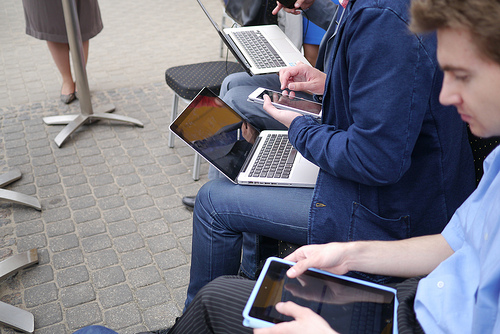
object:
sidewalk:
[1, 0, 225, 334]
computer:
[170, 87, 320, 188]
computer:
[248, 82, 323, 118]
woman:
[23, 0, 103, 106]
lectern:
[46, 0, 142, 146]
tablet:
[241, 254, 413, 332]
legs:
[53, 0, 117, 117]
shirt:
[410, 143, 499, 334]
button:
[436, 281, 444, 288]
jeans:
[186, 161, 362, 294]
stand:
[35, 0, 142, 150]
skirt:
[22, 0, 110, 43]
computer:
[197, 0, 312, 74]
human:
[79, 0, 496, 333]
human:
[179, 0, 480, 303]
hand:
[277, 59, 328, 94]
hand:
[258, 93, 297, 126]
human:
[181, 0, 342, 208]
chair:
[162, 0, 270, 180]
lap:
[189, 179, 280, 240]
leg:
[42, 114, 80, 124]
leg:
[95, 106, 120, 113]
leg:
[93, 114, 146, 126]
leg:
[54, 115, 85, 146]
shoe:
[60, 83, 73, 103]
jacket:
[286, 0, 479, 245]